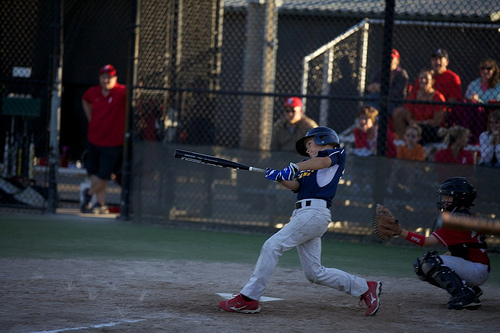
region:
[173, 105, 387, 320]
a batter swings the bat at a baseball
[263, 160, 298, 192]
the player has baseball gloves on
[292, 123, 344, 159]
the batter is wearing a protective helmet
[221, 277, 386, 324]
the batter has red shoes on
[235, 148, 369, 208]
the batter has a blue and white shirt on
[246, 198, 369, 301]
the boy's pants are white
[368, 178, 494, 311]
the catcher has a baseball mitt in his hand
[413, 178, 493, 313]
the catcher has protective gear on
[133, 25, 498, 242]
a high chain link fence is behind home plate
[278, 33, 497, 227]
spectators are sitting in the stands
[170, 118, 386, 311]
kid playing baseball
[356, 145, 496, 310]
catcher behind the batter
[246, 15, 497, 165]
people in the stands watching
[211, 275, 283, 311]
homeplate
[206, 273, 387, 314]
the batter is wearing red shoes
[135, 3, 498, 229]
chainlink fence separating players from people in the stands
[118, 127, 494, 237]
fence cover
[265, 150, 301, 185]
batter is wearing blue batting gloves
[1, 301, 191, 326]
third baseline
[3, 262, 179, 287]
first baseline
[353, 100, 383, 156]
spectator sitting in stands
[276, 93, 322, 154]
spectator sitting in stands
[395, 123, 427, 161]
spectator sitting in stands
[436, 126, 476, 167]
spectator sitting in stands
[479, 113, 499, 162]
spectator sitting in stands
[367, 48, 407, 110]
spectator sitting in stands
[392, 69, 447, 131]
spectator sitting in stands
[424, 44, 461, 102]
spectator sitting in stands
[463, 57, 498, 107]
spectator sitting in stands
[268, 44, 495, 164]
spectators sitting in stands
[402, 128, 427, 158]
person in the stand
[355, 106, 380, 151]
person in the stand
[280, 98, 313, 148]
person in the stand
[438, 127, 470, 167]
person in the stand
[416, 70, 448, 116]
person in the stand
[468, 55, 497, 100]
person in the stand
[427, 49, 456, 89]
person in the stand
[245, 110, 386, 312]
player on the field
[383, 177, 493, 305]
player on the field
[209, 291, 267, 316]
shoe on the player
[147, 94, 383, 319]
Baseball player with a bat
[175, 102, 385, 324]
Baseball player swinging a bat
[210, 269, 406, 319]
Red sneakers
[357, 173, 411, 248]
Baseball glove on a hand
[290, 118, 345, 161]
Baseball player wearing a helmet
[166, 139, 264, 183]
Black baseball bat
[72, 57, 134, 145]
A man wearing a red cap and t-shit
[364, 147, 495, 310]
Baseball catcher with a helmet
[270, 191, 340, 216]
Black belt with white pants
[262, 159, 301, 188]
Blue and white gloves in hands